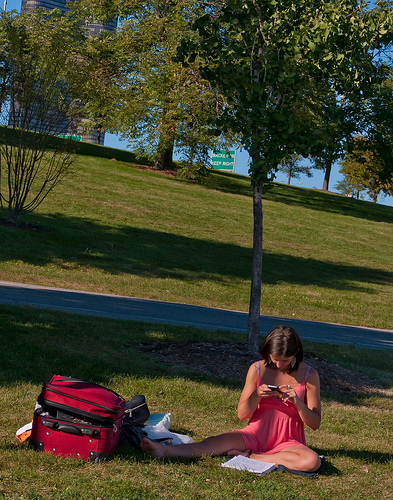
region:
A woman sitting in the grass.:
[137, 329, 345, 483]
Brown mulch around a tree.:
[141, 339, 383, 397]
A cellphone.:
[266, 379, 279, 394]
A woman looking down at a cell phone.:
[139, 318, 343, 478]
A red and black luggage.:
[30, 369, 129, 463]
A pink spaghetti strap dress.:
[236, 349, 316, 461]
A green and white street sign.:
[208, 144, 236, 172]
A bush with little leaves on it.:
[7, 15, 92, 226]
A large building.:
[11, 2, 123, 147]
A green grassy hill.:
[2, 123, 391, 498]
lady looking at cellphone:
[229, 307, 333, 493]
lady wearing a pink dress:
[216, 320, 337, 469]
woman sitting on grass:
[134, 294, 341, 498]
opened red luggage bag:
[14, 363, 140, 471]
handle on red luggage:
[44, 413, 100, 440]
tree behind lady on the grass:
[159, 1, 344, 369]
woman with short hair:
[249, 322, 311, 375]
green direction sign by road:
[202, 140, 240, 174]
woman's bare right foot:
[133, 434, 167, 463]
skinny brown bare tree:
[1, 102, 75, 224]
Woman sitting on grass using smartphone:
[142, 325, 322, 476]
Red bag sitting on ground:
[30, 374, 124, 461]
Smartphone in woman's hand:
[266, 383, 279, 389]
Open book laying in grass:
[222, 453, 274, 476]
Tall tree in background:
[182, 2, 391, 355]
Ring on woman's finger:
[286, 382, 292, 388]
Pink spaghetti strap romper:
[237, 361, 310, 454]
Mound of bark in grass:
[121, 335, 384, 396]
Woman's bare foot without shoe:
[138, 435, 163, 459]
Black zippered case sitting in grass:
[126, 393, 150, 424]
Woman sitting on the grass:
[141, 311, 334, 488]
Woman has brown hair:
[255, 321, 306, 376]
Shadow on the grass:
[1, 194, 390, 302]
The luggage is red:
[27, 357, 126, 471]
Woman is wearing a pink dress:
[231, 319, 317, 456]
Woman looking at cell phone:
[253, 318, 306, 406]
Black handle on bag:
[36, 412, 101, 441]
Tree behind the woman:
[175, 0, 377, 354]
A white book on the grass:
[218, 451, 280, 477]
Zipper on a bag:
[122, 403, 138, 423]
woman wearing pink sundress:
[231, 320, 324, 475]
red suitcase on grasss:
[28, 367, 124, 479]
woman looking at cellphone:
[238, 311, 319, 433]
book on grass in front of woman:
[224, 314, 323, 491]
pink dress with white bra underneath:
[238, 350, 311, 483]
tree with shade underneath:
[7, 44, 392, 416]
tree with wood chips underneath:
[173, 0, 353, 397]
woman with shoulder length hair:
[256, 323, 307, 383]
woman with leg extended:
[138, 321, 345, 498]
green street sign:
[200, 134, 251, 192]